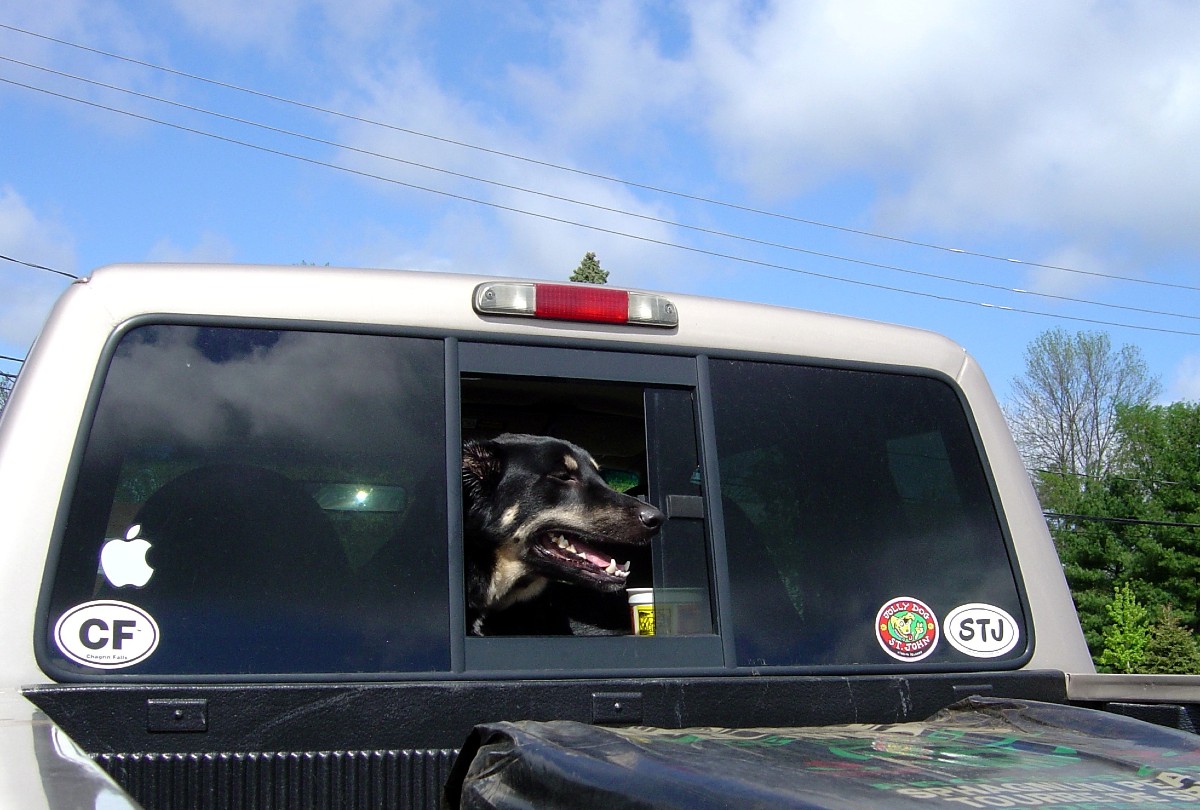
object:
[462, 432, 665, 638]
dog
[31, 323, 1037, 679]
window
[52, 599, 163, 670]
logo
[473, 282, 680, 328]
light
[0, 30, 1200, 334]
lines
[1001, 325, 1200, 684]
trees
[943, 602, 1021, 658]
sticker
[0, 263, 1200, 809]
truck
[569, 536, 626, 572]
tongue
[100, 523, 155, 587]
decal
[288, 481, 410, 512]
mirror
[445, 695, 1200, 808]
tarp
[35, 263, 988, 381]
top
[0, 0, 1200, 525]
clouds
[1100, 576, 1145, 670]
leaves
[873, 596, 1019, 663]
stickers